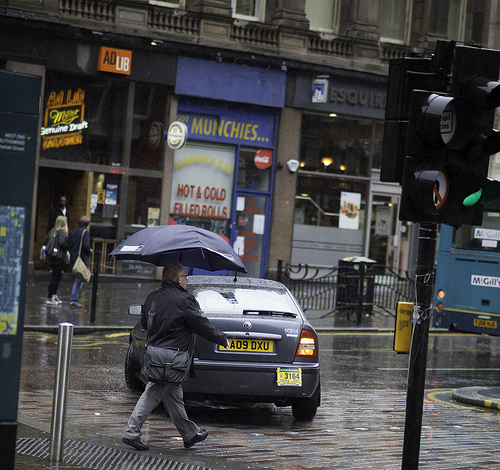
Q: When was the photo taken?
A: Day time.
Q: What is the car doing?
A: Driving.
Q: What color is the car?
A: Gray.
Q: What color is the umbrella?
A: Black.